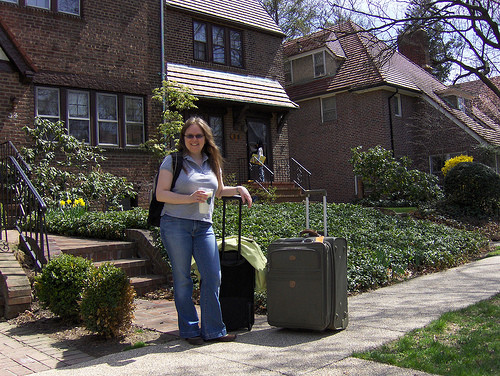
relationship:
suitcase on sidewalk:
[266, 185, 350, 332] [21, 253, 499, 374]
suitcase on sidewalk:
[217, 192, 258, 333] [21, 253, 499, 374]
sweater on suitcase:
[187, 234, 266, 292] [217, 192, 258, 333]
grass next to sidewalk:
[356, 291, 500, 375] [21, 253, 499, 374]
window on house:
[35, 84, 62, 148] [1, 1, 316, 210]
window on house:
[65, 86, 93, 144] [1, 1, 316, 210]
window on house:
[93, 90, 121, 148] [1, 1, 316, 210]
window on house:
[123, 93, 148, 145] [1, 1, 316, 210]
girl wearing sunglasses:
[154, 114, 255, 345] [184, 132, 208, 139]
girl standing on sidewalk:
[154, 114, 255, 345] [21, 253, 499, 374]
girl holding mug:
[154, 114, 255, 345] [196, 187, 218, 218]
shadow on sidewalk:
[49, 324, 196, 371] [21, 253, 499, 374]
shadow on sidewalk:
[235, 324, 343, 351] [21, 253, 499, 374]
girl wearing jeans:
[154, 114, 255, 345] [159, 213, 228, 341]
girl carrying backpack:
[154, 114, 255, 345] [145, 150, 184, 227]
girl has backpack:
[154, 114, 255, 345] [145, 150, 184, 227]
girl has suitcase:
[154, 114, 255, 345] [266, 185, 350, 332]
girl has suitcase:
[154, 114, 255, 345] [217, 192, 258, 333]